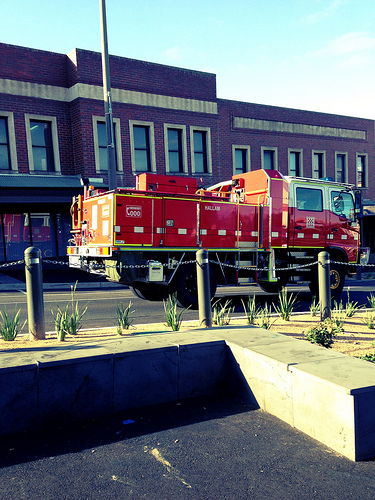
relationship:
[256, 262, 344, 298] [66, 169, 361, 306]
front wheels of truck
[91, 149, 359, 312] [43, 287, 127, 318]
truck in road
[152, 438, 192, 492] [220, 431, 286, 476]
markings on cement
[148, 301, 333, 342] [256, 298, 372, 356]
plants in dirt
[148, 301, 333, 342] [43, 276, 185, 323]
plants by road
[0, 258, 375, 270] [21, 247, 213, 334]
chain connecting poles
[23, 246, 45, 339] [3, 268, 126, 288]
pole by sidewalk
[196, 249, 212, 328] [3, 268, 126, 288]
pole by sidewalk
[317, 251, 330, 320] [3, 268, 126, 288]
pole by sidewalk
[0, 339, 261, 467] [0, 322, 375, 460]
shadow cast by ledge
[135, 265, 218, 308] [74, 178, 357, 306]
wheels by truck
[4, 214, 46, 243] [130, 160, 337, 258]
reflection of truck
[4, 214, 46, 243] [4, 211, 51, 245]
reflection in window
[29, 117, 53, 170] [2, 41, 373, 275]
window of building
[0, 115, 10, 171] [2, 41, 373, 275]
window of building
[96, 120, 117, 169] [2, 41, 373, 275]
window of building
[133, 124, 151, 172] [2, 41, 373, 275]
window of building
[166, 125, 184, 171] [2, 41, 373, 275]
window of building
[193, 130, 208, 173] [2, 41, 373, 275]
window of building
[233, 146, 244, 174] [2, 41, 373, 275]
window of building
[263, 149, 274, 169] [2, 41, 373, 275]
window of building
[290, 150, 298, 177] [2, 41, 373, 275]
window of building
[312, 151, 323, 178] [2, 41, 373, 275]
window of building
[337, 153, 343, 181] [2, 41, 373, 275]
window of building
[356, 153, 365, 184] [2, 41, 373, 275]
window of building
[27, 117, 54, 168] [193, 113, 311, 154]
window of building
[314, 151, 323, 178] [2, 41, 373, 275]
window of building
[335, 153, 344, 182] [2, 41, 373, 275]
window of building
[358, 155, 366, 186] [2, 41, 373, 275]
window of building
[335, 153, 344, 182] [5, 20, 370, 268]
window of building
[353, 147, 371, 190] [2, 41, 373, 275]
window of building